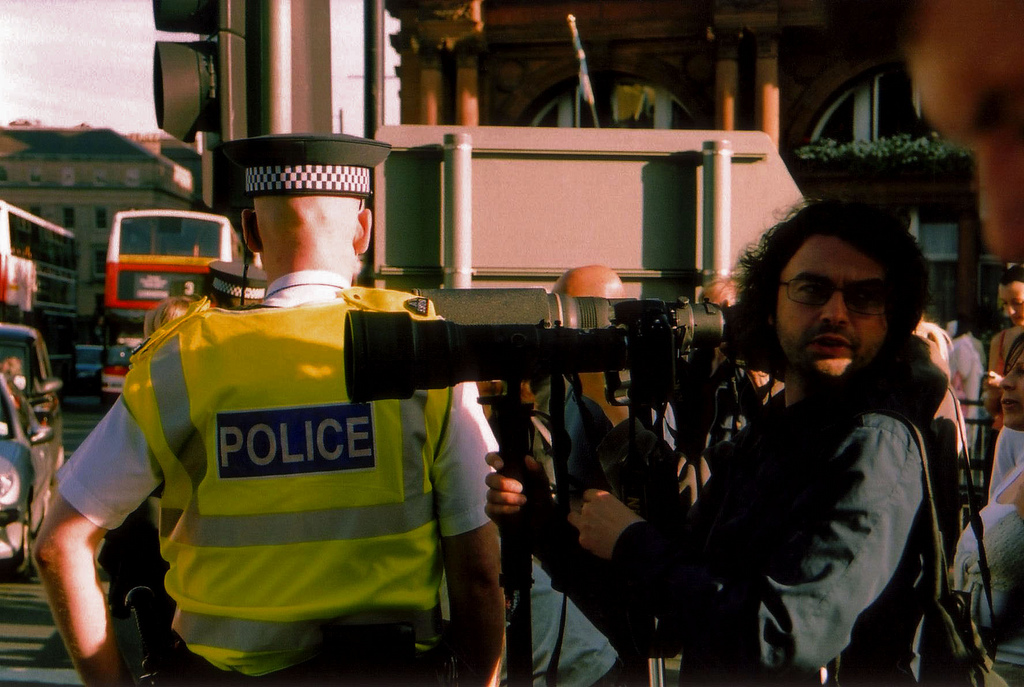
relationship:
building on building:
[5, 118, 205, 321] [378, 3, 1021, 335]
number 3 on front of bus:
[177, 272, 201, 302] [100, 205, 240, 398]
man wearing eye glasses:
[581, 219, 1010, 682] [770, 269, 895, 318]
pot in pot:
[785, 162, 985, 226] [785, 162, 985, 226]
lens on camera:
[340, 300, 369, 412] [539, 363, 632, 560]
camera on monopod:
[539, 363, 632, 560] [469, 374, 549, 596]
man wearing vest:
[28, 127, 510, 684] [118, 281, 455, 677]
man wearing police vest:
[28, 127, 510, 684] [113, 278, 458, 678]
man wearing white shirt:
[28, 127, 510, 684] [53, 265, 505, 547]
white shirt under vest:
[53, 265, 505, 547] [118, 281, 455, 677]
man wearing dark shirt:
[581, 219, 1010, 682] [530, 386, 933, 681]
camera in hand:
[539, 363, 632, 560] [476, 440, 556, 524]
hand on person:
[476, 440, 556, 524] [978, 257, 1020, 410]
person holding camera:
[978, 257, 1020, 410] [539, 363, 632, 560]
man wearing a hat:
[28, 127, 510, 684] [189, 120, 452, 193]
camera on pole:
[539, 363, 632, 560] [539, 363, 632, 560]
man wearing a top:
[581, 219, 1009, 682] [581, 407, 1009, 683]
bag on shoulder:
[879, 421, 1007, 614] [879, 421, 1007, 614]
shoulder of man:
[879, 421, 1007, 614] [623, 246, 1007, 614]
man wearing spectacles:
[581, 219, 1010, 682] [774, 268, 898, 313]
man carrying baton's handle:
[28, 127, 510, 684] [125, 581, 180, 684]